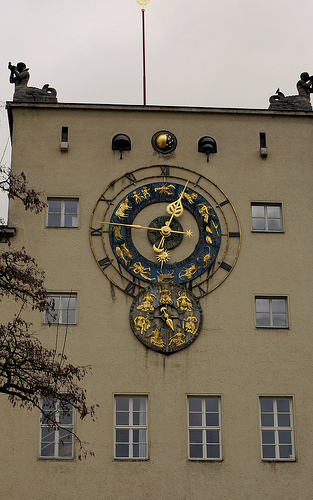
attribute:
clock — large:
[85, 163, 243, 357]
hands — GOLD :
[92, 175, 200, 262]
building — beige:
[2, 99, 310, 498]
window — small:
[249, 202, 281, 232]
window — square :
[258, 394, 296, 461]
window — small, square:
[44, 195, 78, 227]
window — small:
[249, 198, 283, 231]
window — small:
[253, 293, 289, 326]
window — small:
[40, 289, 78, 322]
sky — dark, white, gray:
[153, 4, 311, 67]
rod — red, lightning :
[133, 10, 154, 109]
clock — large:
[92, 158, 245, 321]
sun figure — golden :
[155, 246, 172, 265]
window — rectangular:
[185, 394, 222, 460]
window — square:
[242, 190, 299, 234]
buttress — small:
[251, 128, 276, 166]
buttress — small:
[55, 122, 73, 150]